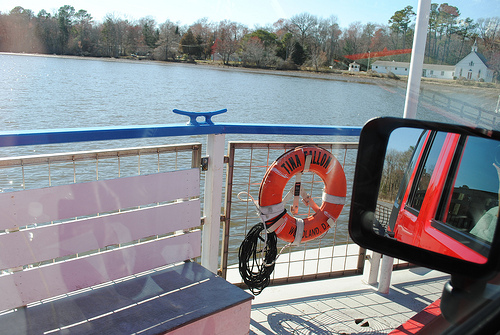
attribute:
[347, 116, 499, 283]
mirror — side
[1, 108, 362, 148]
rail — blue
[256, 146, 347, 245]
lifesaver — orange, round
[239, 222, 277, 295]
rope — black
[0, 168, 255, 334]
bench — white, wooden, pink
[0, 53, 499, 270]
water — calm, blue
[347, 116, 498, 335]
car — red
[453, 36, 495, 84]
church — white, small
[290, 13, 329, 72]
trees — leafless, bare, brown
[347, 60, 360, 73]
gazebo — white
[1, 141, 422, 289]
fence — silver, metal, wooden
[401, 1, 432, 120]
pole — white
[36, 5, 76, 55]
tree — green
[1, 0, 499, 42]
sky — blue, clear